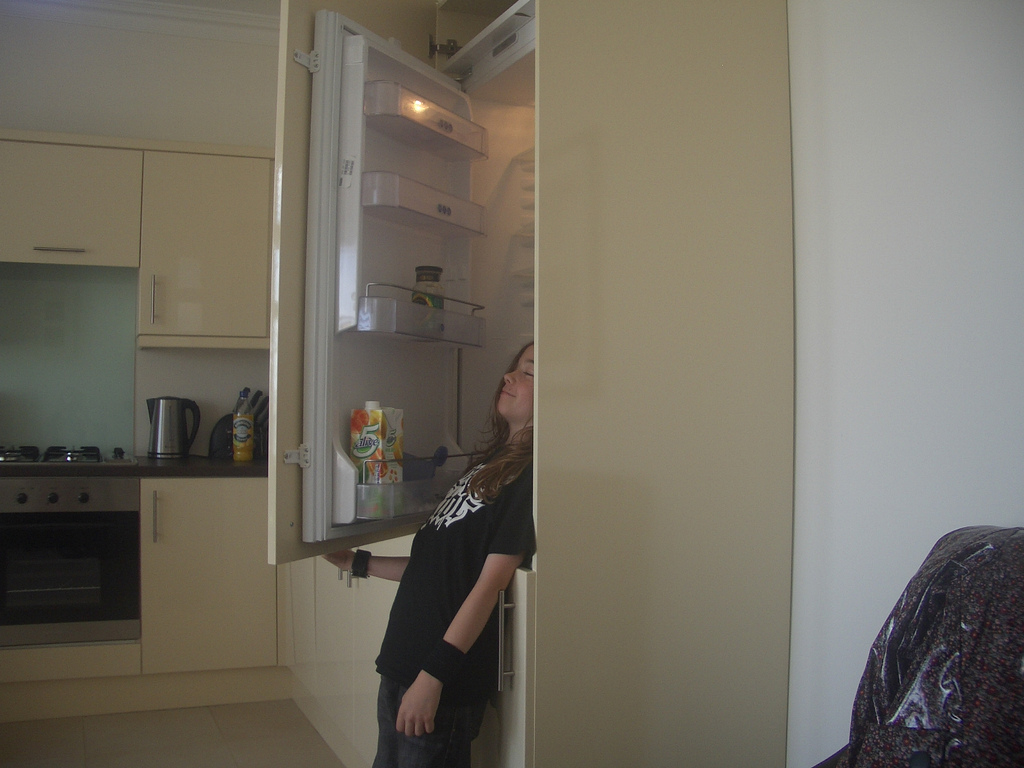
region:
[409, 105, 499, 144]
shelf in the fridge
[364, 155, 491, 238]
shelf in the fridge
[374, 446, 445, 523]
shelf in the fridge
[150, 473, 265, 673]
cabinet on the wall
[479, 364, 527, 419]
head of the woman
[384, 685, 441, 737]
hand of the woman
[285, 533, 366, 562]
hand of the woman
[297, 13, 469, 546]
an open refrigerator door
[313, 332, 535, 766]
a girl leaning into refrigerator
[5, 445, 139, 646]
a built-in stovetop oven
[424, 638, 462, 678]
a black wrist band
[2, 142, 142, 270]
a kitchen cabinet door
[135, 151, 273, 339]
a kitchen cabinet door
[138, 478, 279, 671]
a kitchen cabinet door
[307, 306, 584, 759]
this is a woman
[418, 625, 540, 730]
the woman has a wrist band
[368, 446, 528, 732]
the shirt is black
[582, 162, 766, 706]
the wall is tan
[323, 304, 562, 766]
girl is leaning in the fridge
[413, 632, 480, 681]
thick black band around the wrist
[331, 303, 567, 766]
girl is wearing all black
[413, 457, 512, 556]
white design on the front of the shirt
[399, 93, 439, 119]
small light glare in the fridge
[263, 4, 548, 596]
fridge door is open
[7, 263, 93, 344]
shadow on the wall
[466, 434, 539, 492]
hair is laying over the shoulder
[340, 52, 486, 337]
shelves inside the fridge door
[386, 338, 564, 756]
young girl in refrigerator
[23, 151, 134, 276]
tan colored kitchen cabinet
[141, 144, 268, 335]
tan colored kitchen cabinet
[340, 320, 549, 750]
woman wearing black shirt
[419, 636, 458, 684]
black wristband the woman is wearing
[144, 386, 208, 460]
kettle on the countertop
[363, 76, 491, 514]
shelves in the fridge door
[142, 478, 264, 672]
cabinet beside the oven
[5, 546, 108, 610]
view window in the oven door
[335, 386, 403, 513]
juice container on the fridge door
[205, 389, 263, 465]
knife block on the countertop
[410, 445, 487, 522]
white logo on the black shirt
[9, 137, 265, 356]
cabinets above the countertop